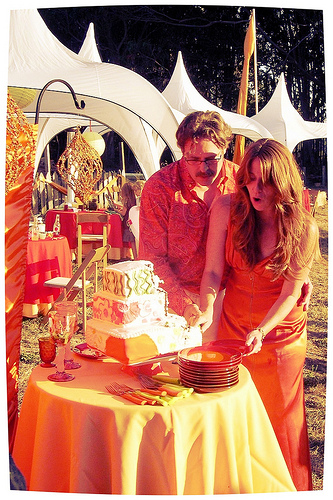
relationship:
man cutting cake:
[150, 100, 230, 316] [89, 261, 178, 362]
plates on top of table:
[176, 347, 223, 391] [60, 385, 105, 414]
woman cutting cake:
[213, 149, 297, 350] [89, 261, 178, 362]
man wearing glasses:
[150, 100, 230, 316] [179, 153, 223, 170]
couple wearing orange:
[160, 123, 291, 278] [232, 271, 258, 290]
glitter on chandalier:
[73, 151, 83, 158] [60, 131, 102, 196]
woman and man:
[213, 149, 297, 350] [150, 100, 230, 316]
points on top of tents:
[78, 17, 96, 40] [40, 32, 177, 116]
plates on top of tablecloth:
[176, 347, 223, 391] [203, 391, 229, 401]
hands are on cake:
[185, 310, 208, 324] [89, 261, 178, 362]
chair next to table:
[68, 218, 112, 260] [60, 385, 105, 414]